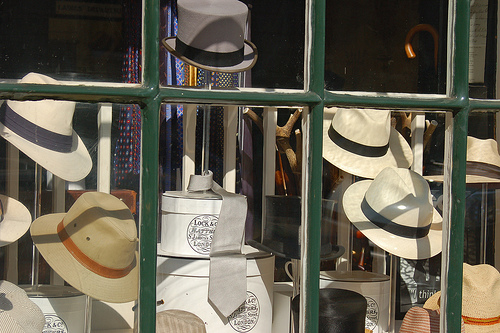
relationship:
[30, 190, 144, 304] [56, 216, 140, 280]
hat has band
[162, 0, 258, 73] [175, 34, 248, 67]
hat has band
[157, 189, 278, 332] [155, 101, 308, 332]
boxes on window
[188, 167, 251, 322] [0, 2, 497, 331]
tie in display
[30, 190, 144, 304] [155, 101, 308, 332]
hat in window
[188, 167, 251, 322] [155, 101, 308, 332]
tie in window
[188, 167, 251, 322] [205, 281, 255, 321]
tie has end